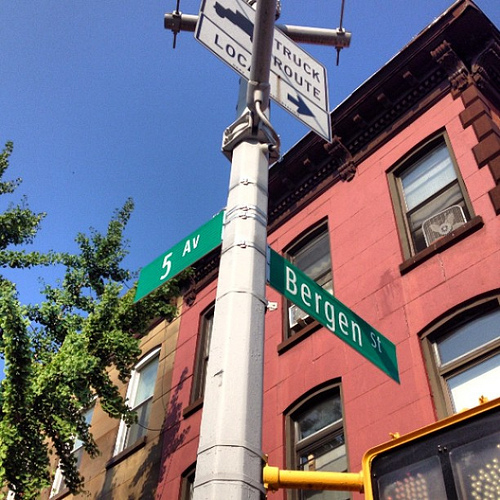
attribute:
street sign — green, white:
[131, 210, 225, 300]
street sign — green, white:
[266, 245, 400, 384]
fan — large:
[421, 202, 466, 247]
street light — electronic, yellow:
[262, 399, 500, 500]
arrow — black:
[287, 92, 314, 118]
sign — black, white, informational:
[193, 1, 332, 144]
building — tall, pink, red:
[154, 1, 500, 499]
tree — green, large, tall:
[0, 139, 196, 500]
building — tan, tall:
[1, 286, 184, 500]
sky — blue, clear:
[2, 1, 500, 386]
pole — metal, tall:
[165, 3, 344, 499]